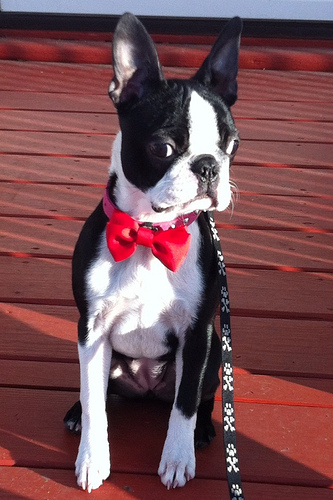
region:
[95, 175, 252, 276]
red bow tie around dog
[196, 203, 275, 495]
black and white leash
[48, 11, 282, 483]
black and white dog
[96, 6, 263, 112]
dogs ears standing up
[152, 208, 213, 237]
studs on bow tie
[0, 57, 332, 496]
wooden floor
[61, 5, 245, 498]
black and white boston terrier dog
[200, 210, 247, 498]
black and white dog leash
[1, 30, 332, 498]
red colored wooden deck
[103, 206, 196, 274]
red bowtie around neck of dog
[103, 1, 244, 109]
two black dog ears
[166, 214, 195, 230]
silver studs on dog collar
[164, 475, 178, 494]
nails on dow paws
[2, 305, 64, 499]
shadow on deck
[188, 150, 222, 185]
black dog nose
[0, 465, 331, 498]
red wooden plank on floor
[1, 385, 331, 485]
red wooden plank on floor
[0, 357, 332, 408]
red wooden plank on floor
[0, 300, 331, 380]
red wooden plank on floor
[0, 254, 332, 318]
red wooden plank on floor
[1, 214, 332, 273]
red wooden plank on floor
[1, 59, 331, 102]
red wooden plank on floor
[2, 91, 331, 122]
red wooden plank on floor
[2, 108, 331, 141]
red wooden plank on floor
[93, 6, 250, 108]
ears of the dog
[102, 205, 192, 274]
a bowtie the dog is wearing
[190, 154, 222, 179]
a nose of the dog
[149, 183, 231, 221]
a mouth of the dog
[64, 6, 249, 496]
a black and white dog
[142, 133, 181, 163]
an eye of the dog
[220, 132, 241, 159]
an eye of the dog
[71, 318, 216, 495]
legs of dog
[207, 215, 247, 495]
leash of the dog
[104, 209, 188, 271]
red bow tie around the dog's neck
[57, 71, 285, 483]
dog sitting on a red painted deck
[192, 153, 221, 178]
black nose of the dog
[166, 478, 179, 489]
to front claws of the dog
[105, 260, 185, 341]
white chest fur of the dog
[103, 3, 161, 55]
pointed ear of the dog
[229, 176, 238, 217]
white whiskers coming from the dog's face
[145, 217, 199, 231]
red collar with silver studs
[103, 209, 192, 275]
bright red bow tie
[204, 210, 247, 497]
black leash with paw and crossbones print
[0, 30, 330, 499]
sundeck built of redwood slats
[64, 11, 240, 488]
a black and white Boston terrier on a deck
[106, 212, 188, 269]
a red bow tie on the dog's collar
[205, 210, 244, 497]
the dog's black and white leash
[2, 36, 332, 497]
a wooden deck stained red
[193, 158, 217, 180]
the dog's black nose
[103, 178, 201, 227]
the dog's red collar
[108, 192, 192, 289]
a red bow tie on the dog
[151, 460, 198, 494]
the dogs short nails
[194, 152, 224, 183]
the dogs black nose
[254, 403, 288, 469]
the floor is red in color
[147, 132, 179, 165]
the dogs left eye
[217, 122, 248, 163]
the dog's right eye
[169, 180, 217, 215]
the dog's mouth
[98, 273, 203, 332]
the dogs white chest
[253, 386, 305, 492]
the red wooden floor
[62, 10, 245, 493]
Dog wearing a bow-tie.